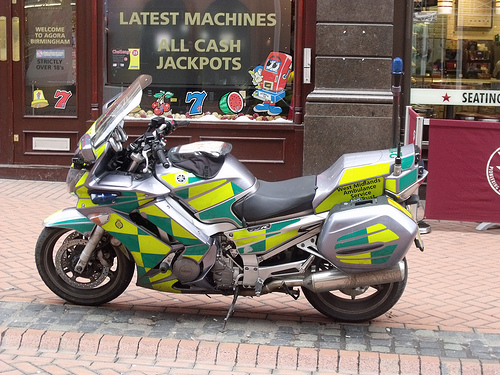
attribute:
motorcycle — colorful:
[33, 73, 430, 323]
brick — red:
[194, 335, 222, 361]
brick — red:
[81, 344, 223, 369]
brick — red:
[19, 330, 46, 353]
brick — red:
[51, 325, 88, 359]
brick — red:
[42, 325, 64, 355]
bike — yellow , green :
[35, 61, 442, 344]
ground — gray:
[1, 175, 498, 374]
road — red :
[0, 178, 500, 373]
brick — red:
[96, 336, 120, 361]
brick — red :
[449, 259, 469, 268]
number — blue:
[184, 89, 213, 116]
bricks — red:
[151, 338, 182, 363]